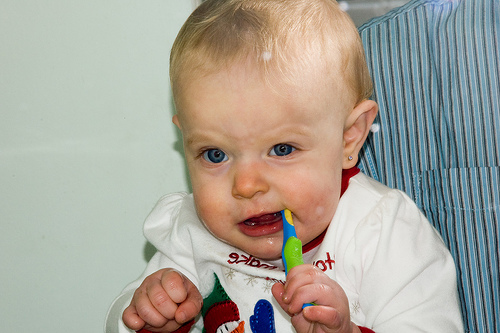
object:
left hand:
[271, 264, 359, 333]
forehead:
[176, 64, 314, 133]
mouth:
[233, 210, 294, 237]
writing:
[225, 251, 278, 270]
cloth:
[370, 227, 422, 298]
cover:
[355, 0, 500, 332]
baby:
[106, 0, 468, 333]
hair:
[168, 0, 375, 102]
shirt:
[106, 166, 471, 333]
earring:
[346, 152, 354, 161]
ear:
[341, 96, 379, 171]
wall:
[1, 0, 199, 332]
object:
[280, 209, 317, 310]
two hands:
[121, 261, 353, 333]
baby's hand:
[121, 265, 205, 332]